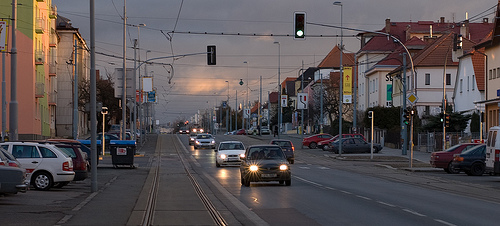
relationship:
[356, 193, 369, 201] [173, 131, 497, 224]
line on street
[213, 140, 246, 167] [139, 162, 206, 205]
car on street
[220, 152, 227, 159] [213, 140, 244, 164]
headlight on car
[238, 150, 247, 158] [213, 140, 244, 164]
headlight on car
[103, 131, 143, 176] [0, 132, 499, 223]
bin side of street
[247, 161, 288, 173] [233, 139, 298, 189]
headlights on car